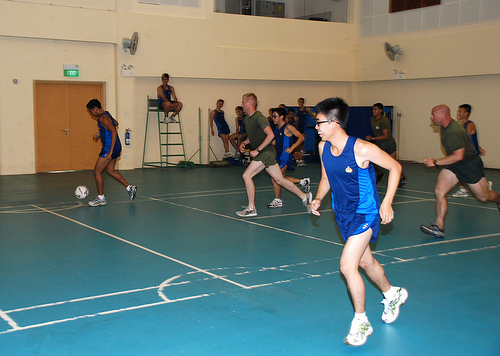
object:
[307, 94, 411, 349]
man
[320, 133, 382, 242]
uniform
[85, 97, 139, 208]
player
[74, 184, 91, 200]
ball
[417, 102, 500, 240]
man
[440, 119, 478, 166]
green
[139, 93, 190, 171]
chair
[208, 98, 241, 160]
person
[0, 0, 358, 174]
wall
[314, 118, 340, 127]
glasses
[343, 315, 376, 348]
shoes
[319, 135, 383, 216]
jersey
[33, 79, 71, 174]
doors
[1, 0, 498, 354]
gym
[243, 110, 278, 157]
shirt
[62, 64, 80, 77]
exit sign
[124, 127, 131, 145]
fire extinguisher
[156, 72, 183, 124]
person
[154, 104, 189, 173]
ladder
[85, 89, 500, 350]
group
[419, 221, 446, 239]
shoe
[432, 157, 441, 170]
watch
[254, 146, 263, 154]
wrist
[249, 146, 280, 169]
shorts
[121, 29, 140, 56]
fan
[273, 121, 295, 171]
blue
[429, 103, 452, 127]
head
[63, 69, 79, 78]
green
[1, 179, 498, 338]
pattern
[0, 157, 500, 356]
floor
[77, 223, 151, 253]
lines